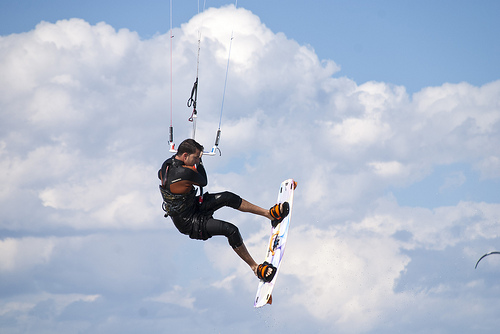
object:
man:
[157, 139, 290, 283]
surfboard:
[252, 179, 296, 308]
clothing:
[158, 155, 244, 249]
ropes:
[169, 0, 230, 156]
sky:
[0, 1, 500, 334]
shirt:
[158, 155, 208, 194]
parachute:
[474, 251, 499, 267]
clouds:
[0, 7, 495, 230]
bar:
[169, 142, 218, 156]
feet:
[269, 201, 290, 227]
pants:
[188, 190, 243, 249]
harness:
[160, 155, 181, 193]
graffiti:
[269, 230, 279, 257]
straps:
[255, 261, 277, 282]